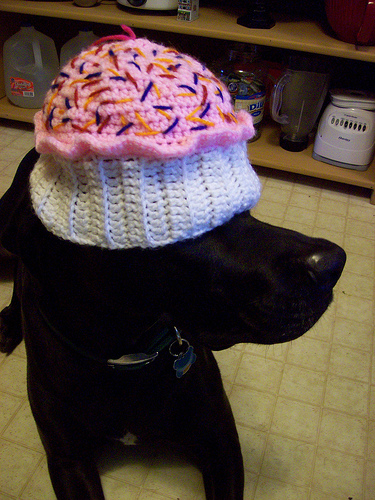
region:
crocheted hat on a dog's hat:
[21, 29, 268, 251]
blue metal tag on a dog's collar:
[162, 322, 202, 388]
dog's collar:
[28, 304, 179, 380]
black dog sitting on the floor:
[0, 136, 351, 498]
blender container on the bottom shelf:
[274, 47, 323, 153]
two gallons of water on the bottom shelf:
[1, 15, 105, 118]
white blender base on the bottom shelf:
[311, 84, 374, 174]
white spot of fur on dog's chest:
[115, 427, 142, 448]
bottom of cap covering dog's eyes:
[24, 142, 267, 255]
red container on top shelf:
[320, 0, 374, 51]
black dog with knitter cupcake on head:
[27, 53, 374, 493]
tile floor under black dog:
[63, 306, 374, 473]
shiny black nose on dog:
[295, 229, 361, 278]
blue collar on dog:
[94, 345, 209, 383]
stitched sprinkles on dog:
[99, 43, 179, 124]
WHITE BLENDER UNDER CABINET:
[307, 78, 374, 151]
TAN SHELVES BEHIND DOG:
[99, 8, 369, 156]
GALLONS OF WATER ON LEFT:
[10, 30, 111, 91]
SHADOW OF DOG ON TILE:
[236, 412, 300, 477]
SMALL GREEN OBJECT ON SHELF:
[170, 7, 198, 28]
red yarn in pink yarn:
[122, 70, 140, 93]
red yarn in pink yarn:
[142, 59, 157, 76]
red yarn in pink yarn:
[199, 83, 206, 107]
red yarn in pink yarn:
[78, 82, 114, 91]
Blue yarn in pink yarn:
[134, 81, 156, 112]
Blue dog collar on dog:
[153, 309, 208, 390]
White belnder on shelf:
[331, 78, 371, 210]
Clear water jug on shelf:
[3, 15, 48, 132]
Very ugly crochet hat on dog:
[10, 11, 350, 320]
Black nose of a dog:
[281, 222, 367, 317]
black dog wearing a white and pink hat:
[0, 15, 352, 486]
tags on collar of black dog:
[159, 322, 202, 375]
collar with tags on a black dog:
[32, 330, 206, 372]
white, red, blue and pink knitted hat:
[23, 11, 268, 250]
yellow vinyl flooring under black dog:
[243, 339, 365, 494]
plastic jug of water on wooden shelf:
[0, 19, 69, 129]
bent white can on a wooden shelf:
[310, 90, 371, 175]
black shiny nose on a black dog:
[292, 235, 353, 312]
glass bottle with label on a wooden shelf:
[214, 60, 271, 143]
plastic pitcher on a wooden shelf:
[257, 58, 329, 159]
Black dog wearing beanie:
[8, 27, 338, 396]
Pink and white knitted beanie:
[20, 38, 265, 227]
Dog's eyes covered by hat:
[12, 130, 300, 273]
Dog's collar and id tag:
[73, 328, 205, 377]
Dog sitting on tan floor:
[13, 117, 345, 492]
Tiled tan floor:
[244, 356, 373, 497]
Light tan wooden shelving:
[233, 10, 373, 190]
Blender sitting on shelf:
[273, 53, 373, 174]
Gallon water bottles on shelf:
[4, 27, 62, 120]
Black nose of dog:
[290, 227, 357, 292]